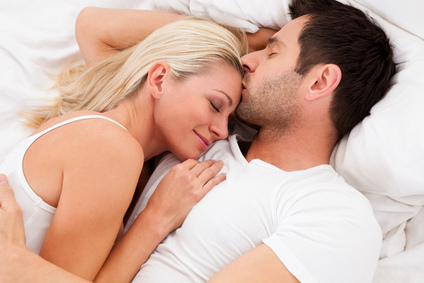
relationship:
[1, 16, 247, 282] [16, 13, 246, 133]
woman with hair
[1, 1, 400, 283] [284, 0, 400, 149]
man has hair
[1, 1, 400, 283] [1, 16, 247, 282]
man with woman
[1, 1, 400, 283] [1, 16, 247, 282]
man kissing woman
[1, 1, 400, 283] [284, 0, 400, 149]
man with hair